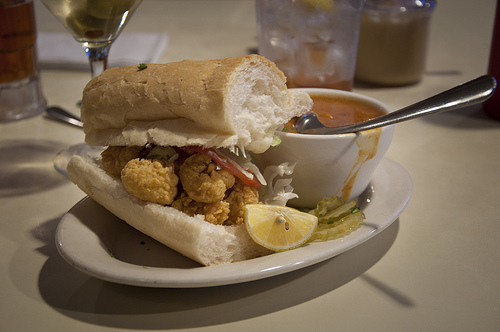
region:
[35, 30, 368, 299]
Food on a plate.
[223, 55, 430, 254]
Soup in the bowl.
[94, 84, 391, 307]
Lemon on the plate.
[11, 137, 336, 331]
White plate on the table.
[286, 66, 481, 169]
Utensil in the soup.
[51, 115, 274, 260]
Shrimp on the sandwich.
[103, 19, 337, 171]
Bread on the sandwich.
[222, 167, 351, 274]
Yellow lemon on the plate.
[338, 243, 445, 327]
Shadow on the table.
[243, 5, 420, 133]
Cup on the table.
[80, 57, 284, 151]
The bun of the sandwich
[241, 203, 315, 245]
A small piece of lemon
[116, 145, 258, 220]
Pieces of meat in the sandwich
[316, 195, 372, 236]
Slices of pickle on the plate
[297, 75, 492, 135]
A silver spoon in the bowl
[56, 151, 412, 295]
White plate on the table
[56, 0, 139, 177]
A wine glass on the table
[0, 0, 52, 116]
A cup with brown liquid in it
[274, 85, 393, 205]
A white bowl with soup in it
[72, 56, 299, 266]
A sandwich on the plate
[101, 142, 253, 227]
the sandwich has fried shrimp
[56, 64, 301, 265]
the sandwich has white bread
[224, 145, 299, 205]
the sandwich has has lettuce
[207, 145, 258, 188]
the sandwich has tomato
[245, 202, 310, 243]
a side of lemon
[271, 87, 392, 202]
a bowl of soup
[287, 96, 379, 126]
the soup is orange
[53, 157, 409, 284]
the plate is white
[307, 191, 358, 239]
the pickles are cut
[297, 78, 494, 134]
the spoon is in the bowl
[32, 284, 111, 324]
Small black shadow on a white table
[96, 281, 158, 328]
Small black shadow on a white table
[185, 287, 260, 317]
Small black shadow on a white table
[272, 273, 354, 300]
Small black shadow on a white table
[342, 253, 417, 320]
Small black shadow on a white table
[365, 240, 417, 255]
Small black shadow on a white table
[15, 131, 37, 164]
Small black shadow on a white table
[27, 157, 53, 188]
Small black shadow on a white table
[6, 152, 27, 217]
Small black shadow on a white table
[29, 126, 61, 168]
Small black shadow on a white table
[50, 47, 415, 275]
a sandwich and soup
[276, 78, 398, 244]
a small bowl of soup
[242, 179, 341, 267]
a wedge of lemon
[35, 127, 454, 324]
a white plate with food on it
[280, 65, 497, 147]
a spoon in the soup bowl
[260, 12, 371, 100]
a glass with ice in it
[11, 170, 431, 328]
a shadow on table from plate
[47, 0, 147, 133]
a glass of wine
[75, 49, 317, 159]
top bun of sandwich